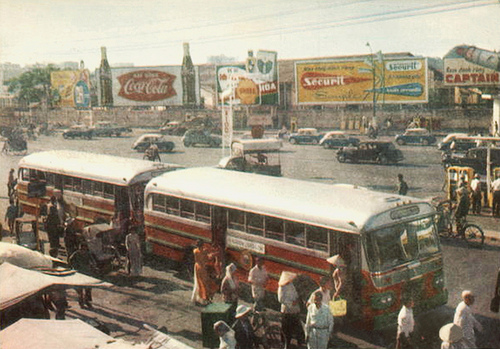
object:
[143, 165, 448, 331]
bus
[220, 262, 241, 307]
person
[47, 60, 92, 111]
billboard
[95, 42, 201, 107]
billboard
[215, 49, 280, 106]
billboard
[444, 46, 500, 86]
billboard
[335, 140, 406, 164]
car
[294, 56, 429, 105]
billboard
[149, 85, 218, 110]
building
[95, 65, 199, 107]
advertisement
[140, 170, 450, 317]
knee pad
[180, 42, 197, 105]
bottle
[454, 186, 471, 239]
man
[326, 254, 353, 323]
lady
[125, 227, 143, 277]
person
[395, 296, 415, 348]
person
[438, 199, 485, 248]
bike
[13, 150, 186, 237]
bus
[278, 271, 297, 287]
hat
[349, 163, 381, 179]
ground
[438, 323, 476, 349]
person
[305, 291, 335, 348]
person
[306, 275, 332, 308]
person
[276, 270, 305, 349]
person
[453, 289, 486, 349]
person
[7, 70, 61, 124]
tree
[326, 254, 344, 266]
hat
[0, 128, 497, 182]
street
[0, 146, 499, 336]
street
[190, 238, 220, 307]
people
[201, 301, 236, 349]
trash bin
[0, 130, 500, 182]
road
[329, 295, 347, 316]
purse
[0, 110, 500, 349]
parking lot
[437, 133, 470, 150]
car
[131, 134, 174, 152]
car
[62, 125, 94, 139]
car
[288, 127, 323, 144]
car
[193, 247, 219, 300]
dress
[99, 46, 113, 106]
bottle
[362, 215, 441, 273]
windshield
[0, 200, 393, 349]
sidewalk